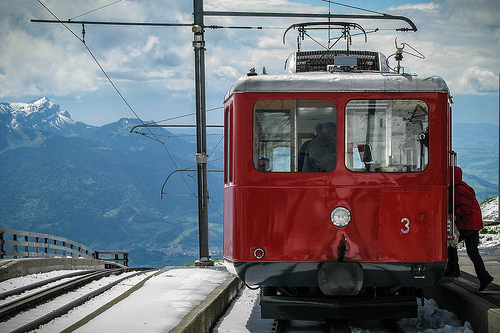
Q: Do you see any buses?
A: No, there are no buses.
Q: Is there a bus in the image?
A: No, there are no buses.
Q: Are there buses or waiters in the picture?
A: No, there are no buses or waiters.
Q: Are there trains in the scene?
A: Yes, there is a train.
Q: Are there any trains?
A: Yes, there is a train.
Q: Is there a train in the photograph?
A: Yes, there is a train.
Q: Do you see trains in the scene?
A: Yes, there is a train.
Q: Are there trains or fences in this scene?
A: Yes, there is a train.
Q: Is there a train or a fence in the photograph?
A: Yes, there is a train.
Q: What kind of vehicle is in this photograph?
A: The vehicle is a train.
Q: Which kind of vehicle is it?
A: The vehicle is a train.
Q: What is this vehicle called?
A: That is a train.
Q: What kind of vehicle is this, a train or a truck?
A: That is a train.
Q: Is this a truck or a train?
A: This is a train.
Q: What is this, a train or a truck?
A: This is a train.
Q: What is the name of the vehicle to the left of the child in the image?
A: The vehicle is a train.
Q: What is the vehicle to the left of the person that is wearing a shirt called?
A: The vehicle is a train.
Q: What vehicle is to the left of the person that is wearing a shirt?
A: The vehicle is a train.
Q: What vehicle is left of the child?
A: The vehicle is a train.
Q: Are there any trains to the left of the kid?
A: Yes, there is a train to the left of the kid.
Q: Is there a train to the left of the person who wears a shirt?
A: Yes, there is a train to the left of the kid.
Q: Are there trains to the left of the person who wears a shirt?
A: Yes, there is a train to the left of the kid.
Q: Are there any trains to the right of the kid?
A: No, the train is to the left of the kid.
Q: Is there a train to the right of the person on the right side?
A: No, the train is to the left of the kid.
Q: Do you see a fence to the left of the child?
A: No, there is a train to the left of the child.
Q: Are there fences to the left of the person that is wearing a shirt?
A: No, there is a train to the left of the child.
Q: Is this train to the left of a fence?
A: No, the train is to the left of the child.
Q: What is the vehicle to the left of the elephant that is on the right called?
A: The vehicle is a train.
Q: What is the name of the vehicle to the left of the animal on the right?
A: The vehicle is a train.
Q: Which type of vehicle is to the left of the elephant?
A: The vehicle is a train.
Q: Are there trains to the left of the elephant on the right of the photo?
A: Yes, there is a train to the left of the elephant.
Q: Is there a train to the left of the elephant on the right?
A: Yes, there is a train to the left of the elephant.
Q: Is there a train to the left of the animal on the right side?
A: Yes, there is a train to the left of the elephant.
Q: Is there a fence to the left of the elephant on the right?
A: No, there is a train to the left of the elephant.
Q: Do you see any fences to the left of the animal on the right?
A: No, there is a train to the left of the elephant.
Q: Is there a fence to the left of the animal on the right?
A: No, there is a train to the left of the elephant.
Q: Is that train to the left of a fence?
A: No, the train is to the left of the elephant.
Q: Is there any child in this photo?
A: Yes, there is a child.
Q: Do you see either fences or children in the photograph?
A: Yes, there is a child.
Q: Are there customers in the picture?
A: No, there are no customers.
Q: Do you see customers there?
A: No, there are no customers.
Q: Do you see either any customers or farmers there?
A: No, there are no customers or farmers.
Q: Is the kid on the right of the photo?
A: Yes, the kid is on the right of the image.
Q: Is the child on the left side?
A: No, the child is on the right of the image.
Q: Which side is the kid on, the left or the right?
A: The kid is on the right of the image.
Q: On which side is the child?
A: The child is on the right of the image.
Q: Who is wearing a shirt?
A: The kid is wearing a shirt.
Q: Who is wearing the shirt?
A: The kid is wearing a shirt.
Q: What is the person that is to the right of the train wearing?
A: The child is wearing a shirt.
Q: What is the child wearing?
A: The child is wearing a shirt.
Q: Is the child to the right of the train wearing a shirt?
A: Yes, the kid is wearing a shirt.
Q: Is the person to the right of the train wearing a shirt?
A: Yes, the kid is wearing a shirt.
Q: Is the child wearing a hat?
A: No, the child is wearing a shirt.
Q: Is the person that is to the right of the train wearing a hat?
A: No, the child is wearing a shirt.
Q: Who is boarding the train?
A: The child is boarding the train.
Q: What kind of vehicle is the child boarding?
A: The child is boarding the train.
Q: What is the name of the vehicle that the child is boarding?
A: The vehicle is a train.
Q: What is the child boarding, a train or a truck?
A: The child is boarding a train.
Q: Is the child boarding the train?
A: Yes, the child is boarding the train.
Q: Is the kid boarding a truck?
A: No, the kid is boarding the train.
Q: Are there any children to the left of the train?
A: No, the child is to the right of the train.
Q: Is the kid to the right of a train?
A: Yes, the kid is to the right of a train.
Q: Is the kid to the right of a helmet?
A: No, the kid is to the right of a train.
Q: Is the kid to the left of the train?
A: No, the kid is to the right of the train.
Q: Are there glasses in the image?
A: No, there are no glasses.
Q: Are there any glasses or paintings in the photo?
A: No, there are no glasses or paintings.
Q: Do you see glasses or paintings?
A: No, there are no glasses or paintings.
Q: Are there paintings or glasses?
A: No, there are no glasses or paintings.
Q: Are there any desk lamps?
A: No, there are no desk lamps.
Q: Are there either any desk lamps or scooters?
A: No, there are no desk lamps or scooters.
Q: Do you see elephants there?
A: Yes, there is an elephant.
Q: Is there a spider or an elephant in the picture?
A: Yes, there is an elephant.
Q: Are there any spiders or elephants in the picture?
A: Yes, there is an elephant.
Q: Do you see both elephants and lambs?
A: No, there is an elephant but no lambs.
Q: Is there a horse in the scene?
A: No, there are no horses.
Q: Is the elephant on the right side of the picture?
A: Yes, the elephant is on the right of the image.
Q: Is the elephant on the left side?
A: No, the elephant is on the right of the image.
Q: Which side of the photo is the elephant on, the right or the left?
A: The elephant is on the right of the image.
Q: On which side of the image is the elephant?
A: The elephant is on the right of the image.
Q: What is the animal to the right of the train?
A: The animal is an elephant.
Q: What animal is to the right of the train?
A: The animal is an elephant.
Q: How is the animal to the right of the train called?
A: The animal is an elephant.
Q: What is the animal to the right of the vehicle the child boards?
A: The animal is an elephant.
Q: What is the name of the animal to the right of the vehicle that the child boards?
A: The animal is an elephant.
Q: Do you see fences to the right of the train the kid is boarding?
A: No, there is an elephant to the right of the train.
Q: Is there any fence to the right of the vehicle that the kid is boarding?
A: No, there is an elephant to the right of the train.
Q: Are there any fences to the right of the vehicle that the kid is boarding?
A: No, there is an elephant to the right of the train.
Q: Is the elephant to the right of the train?
A: Yes, the elephant is to the right of the train.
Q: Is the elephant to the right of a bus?
A: No, the elephant is to the right of the train.